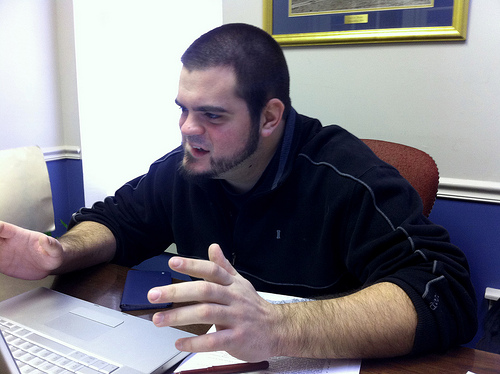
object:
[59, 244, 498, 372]
table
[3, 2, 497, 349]
painted wall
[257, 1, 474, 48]
picture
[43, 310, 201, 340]
trackpad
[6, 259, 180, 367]
laptop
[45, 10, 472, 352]
man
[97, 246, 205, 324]
book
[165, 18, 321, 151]
hair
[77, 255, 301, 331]
desk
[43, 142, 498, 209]
rail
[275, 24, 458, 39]
frame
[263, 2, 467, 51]
picture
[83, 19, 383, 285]
brunette man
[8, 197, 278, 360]
hands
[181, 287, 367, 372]
paper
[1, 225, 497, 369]
table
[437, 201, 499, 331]
wall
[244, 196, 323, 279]
zipper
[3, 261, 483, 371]
desk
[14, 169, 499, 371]
desk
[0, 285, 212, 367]
laptop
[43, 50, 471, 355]
man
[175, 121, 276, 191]
beard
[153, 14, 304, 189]
face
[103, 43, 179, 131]
window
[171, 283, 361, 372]
paper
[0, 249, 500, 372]
desk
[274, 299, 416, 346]
hair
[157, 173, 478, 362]
arm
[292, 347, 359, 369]
papers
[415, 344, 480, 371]
table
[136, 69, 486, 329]
man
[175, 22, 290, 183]
head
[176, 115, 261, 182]
beard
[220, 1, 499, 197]
wall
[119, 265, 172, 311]
book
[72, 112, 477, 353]
shirt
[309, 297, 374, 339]
hair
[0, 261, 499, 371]
table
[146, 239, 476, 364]
arm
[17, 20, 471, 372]
man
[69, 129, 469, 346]
sweater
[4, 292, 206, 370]
laptop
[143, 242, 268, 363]
hand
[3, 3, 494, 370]
office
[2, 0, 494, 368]
room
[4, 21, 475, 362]
person